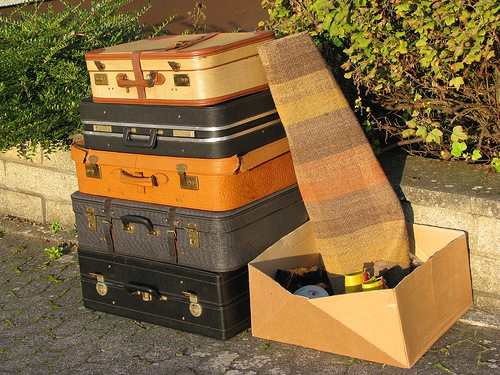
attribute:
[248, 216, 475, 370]
box — cardboard, bent, light brown, brown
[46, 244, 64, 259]
weed — growing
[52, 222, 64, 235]
weed — growing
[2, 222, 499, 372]
road — stone, weedy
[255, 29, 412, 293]
blanket — striped, rolled up, earthtone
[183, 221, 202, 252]
lock — brass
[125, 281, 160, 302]
handle — black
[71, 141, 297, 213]
suitcase — orange, stacked, gold, vintage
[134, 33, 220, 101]
strap — brown, leather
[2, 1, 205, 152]
bush — green, ivy-like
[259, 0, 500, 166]
bush — green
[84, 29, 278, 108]
suitcase — stacked, brown, tan, small, light brown, two toned, vintage, torn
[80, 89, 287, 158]
suitcase — stacked, black, gray, vintage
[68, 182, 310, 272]
suitcase — stacked, gray, large, grey, vintage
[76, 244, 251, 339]
suitcase — stacked, black, vintage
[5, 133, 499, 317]
retaining wall — stone, grey, beige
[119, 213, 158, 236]
handle — black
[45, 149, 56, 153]
leaf — small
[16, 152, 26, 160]
leaf — small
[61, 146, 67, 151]
leaf — small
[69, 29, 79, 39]
leaf — small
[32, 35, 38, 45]
leaf — small